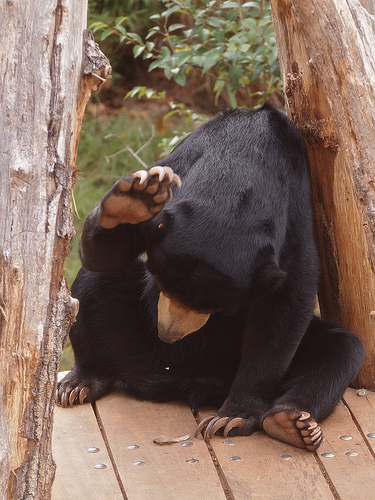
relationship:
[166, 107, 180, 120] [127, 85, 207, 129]
leaf on branch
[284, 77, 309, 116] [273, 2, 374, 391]
bark on trunk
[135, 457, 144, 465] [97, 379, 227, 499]
bolt on board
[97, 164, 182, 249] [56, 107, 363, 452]
paw of bear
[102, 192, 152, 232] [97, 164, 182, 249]
pad on paw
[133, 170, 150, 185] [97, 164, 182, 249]
claw on paw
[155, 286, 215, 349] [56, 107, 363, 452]
nose of bear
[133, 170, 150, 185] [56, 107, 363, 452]
claw of bear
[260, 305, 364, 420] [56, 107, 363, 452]
leg of bear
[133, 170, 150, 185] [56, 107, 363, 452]
claw on bear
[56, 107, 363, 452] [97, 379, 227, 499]
bear on board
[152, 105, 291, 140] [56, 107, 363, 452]
back of bear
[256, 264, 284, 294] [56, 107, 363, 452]
ear of bear